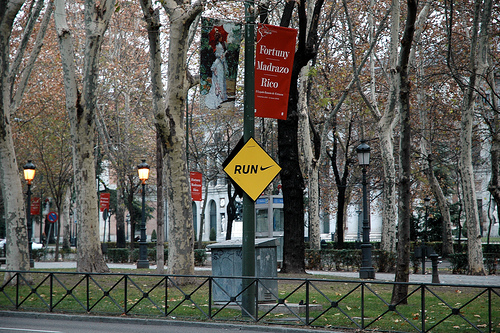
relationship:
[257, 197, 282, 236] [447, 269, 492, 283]
booth next of sidewalk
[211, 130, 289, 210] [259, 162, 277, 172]
sign with symbol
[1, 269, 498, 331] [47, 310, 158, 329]
fence next to street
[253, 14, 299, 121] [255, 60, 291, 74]
banner with lettering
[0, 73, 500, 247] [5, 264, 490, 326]
buidling behind park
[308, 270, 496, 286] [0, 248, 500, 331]
sideway inside park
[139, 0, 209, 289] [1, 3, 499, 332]
tall tree inside park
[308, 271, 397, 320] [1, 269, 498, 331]
grass behind fence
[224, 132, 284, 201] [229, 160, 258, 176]
sign behind writing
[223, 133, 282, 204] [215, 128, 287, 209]
sign on sign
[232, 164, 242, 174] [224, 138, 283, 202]
letter on sign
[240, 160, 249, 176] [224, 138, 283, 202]
letter on sign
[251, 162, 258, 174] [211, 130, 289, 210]
letter on sign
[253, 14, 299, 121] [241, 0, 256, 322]
banner on black pole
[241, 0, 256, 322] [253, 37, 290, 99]
black pole with white lettering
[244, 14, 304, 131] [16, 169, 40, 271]
banner hanging from pole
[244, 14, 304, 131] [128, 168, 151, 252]
banner hanging from pole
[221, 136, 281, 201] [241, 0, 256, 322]
yellow sign on black pole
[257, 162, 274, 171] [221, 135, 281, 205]
logo on sign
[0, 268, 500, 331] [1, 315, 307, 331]
railing by path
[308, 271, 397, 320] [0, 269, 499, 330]
grass growing by guard rail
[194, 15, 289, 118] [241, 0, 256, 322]
flags hanging from black pole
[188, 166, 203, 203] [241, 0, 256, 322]
flags hanging from black pole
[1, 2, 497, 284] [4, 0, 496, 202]
trees covered in brown leaves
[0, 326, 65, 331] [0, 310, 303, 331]
stripe painted on road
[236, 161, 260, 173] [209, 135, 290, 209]
run written on street sign